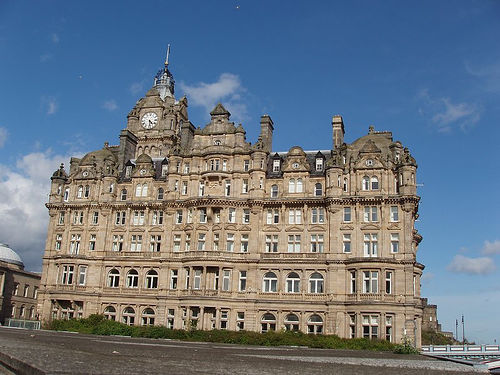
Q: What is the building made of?
A: Stone.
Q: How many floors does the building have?
A: Seven.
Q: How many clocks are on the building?
A: One.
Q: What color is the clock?
A: Black and white.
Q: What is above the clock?
A: Steeple.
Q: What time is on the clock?
A: 4:30.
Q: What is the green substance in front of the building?
A: Shrubs.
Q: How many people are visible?
A: None.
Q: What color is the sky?
A: Blue.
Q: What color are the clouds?
A: White.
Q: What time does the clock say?
A: 4:25.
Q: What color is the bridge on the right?
A: Gray and white.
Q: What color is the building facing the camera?
A: Tan.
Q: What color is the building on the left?
A: Tan.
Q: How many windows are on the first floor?
A: 19.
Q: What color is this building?
A: Beige.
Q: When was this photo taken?
A: Daytime.